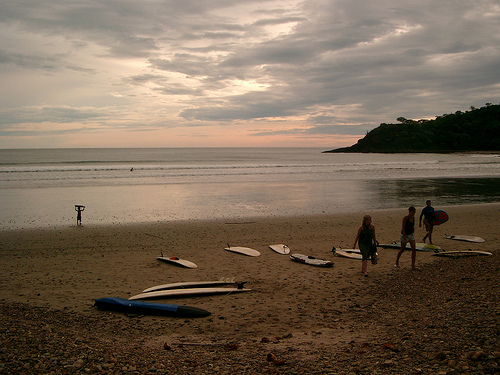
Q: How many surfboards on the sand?
A: Twelve.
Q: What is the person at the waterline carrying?
A: A surfboard.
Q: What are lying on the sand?
A: Surfboards.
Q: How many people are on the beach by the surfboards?
A: Three.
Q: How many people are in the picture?
A: Five.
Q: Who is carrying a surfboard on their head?
A: The person at the waterline.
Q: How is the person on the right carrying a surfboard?
A: Under the arm.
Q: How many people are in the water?
A: Two.